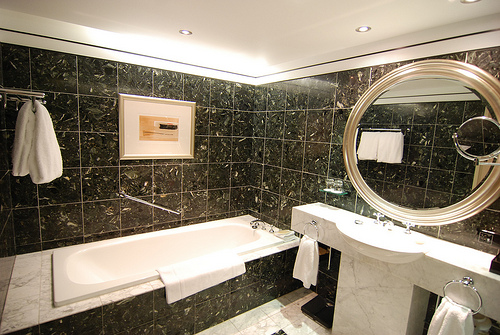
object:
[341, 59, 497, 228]
mirror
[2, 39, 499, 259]
wall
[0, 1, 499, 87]
ceiling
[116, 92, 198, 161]
painting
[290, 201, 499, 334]
counter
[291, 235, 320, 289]
towel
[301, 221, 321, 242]
ring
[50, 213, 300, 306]
bathtub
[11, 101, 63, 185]
towel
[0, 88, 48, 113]
pole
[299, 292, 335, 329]
scale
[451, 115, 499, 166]
mirror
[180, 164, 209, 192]
tile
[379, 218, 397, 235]
facet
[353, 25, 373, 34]
light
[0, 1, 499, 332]
bathroom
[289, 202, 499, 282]
counter-top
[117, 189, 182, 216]
rail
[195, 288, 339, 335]
floor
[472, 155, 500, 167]
swivel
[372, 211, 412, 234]
knobs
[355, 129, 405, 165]
towels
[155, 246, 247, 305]
towel